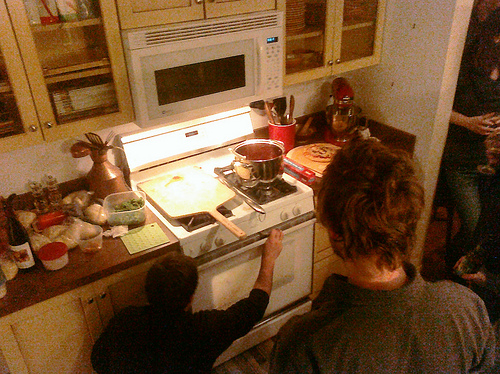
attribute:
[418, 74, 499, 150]
arm —  person's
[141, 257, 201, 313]
head —  person's